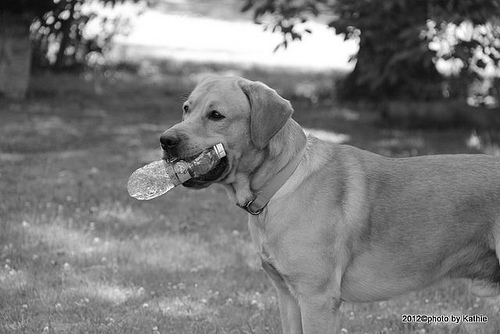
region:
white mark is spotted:
[253, 290, 261, 317]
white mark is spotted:
[240, 290, 258, 310]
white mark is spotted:
[246, 283, 266, 324]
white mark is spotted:
[247, 286, 262, 311]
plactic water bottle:
[112, 148, 255, 199]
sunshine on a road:
[142, 14, 271, 55]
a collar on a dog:
[234, 122, 311, 216]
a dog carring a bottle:
[111, 101, 235, 206]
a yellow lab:
[122, 61, 498, 321]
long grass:
[98, 253, 245, 325]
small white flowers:
[60, 256, 82, 280]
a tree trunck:
[331, 14, 441, 90]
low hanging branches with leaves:
[450, 30, 494, 105]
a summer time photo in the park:
[20, 18, 459, 280]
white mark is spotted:
[144, 296, 154, 321]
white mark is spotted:
[145, 299, 156, 306]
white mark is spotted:
[147, 301, 152, 309]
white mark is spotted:
[142, 298, 152, 311]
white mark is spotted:
[136, 297, 146, 307]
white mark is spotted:
[137, 296, 149, 315]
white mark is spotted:
[142, 298, 147, 308]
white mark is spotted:
[142, 302, 147, 307]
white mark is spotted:
[142, 292, 162, 313]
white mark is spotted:
[136, 300, 151, 322]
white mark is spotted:
[142, 303, 164, 330]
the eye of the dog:
[203, 107, 227, 122]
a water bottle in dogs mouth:
[116, 153, 168, 189]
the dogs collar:
[254, 191, 272, 204]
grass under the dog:
[35, 235, 97, 282]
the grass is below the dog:
[28, 164, 84, 297]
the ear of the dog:
[239, 90, 285, 125]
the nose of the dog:
[161, 130, 186, 145]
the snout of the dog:
[160, 129, 180, 144]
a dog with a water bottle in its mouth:
[151, 82, 440, 330]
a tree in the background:
[377, 22, 431, 92]